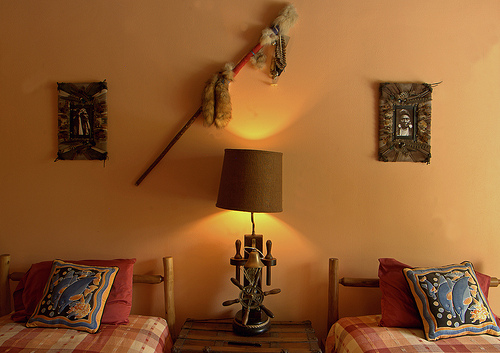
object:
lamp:
[214, 147, 287, 335]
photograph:
[58, 81, 109, 162]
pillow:
[24, 258, 116, 334]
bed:
[0, 255, 176, 353]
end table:
[169, 316, 322, 351]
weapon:
[125, 3, 301, 186]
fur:
[199, 60, 238, 128]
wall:
[0, 0, 498, 322]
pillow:
[20, 255, 135, 325]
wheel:
[219, 267, 287, 326]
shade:
[214, 146, 286, 219]